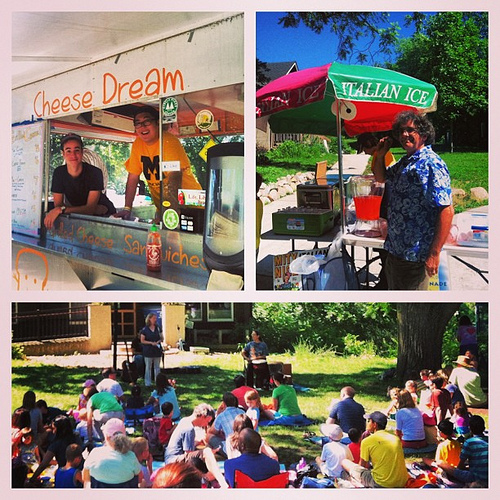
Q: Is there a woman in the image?
A: Yes, there is a woman.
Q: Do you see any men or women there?
A: Yes, there is a woman.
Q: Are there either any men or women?
A: Yes, there is a woman.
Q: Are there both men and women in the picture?
A: Yes, there are both a woman and a man.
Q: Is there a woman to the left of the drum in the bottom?
A: Yes, there is a woman to the left of the drum.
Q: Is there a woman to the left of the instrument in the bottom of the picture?
A: Yes, there is a woman to the left of the drum.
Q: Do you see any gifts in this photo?
A: No, there are no gifts.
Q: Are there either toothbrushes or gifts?
A: No, there are no gifts or toothbrushes.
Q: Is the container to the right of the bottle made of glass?
A: Yes, the container is made of glass.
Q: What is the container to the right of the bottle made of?
A: The container is made of glass.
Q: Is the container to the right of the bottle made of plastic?
A: No, the container is made of glass.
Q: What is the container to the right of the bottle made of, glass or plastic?
A: The container is made of glass.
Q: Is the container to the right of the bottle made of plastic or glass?
A: The container is made of glass.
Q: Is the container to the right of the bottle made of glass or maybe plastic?
A: The container is made of glass.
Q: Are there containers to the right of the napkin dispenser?
A: Yes, there is a container to the right of the napkin dispenser.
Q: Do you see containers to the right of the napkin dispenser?
A: Yes, there is a container to the right of the napkin dispenser.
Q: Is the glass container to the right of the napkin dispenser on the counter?
A: Yes, the container is to the right of the napkin dispenser.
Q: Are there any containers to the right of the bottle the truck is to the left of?
A: Yes, there is a container to the right of the bottle.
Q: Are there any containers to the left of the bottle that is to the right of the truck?
A: No, the container is to the right of the bottle.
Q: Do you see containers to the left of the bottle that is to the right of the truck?
A: No, the container is to the right of the bottle.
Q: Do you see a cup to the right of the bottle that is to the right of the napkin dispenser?
A: No, there is a container to the right of the bottle.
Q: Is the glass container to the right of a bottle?
A: Yes, the container is to the right of a bottle.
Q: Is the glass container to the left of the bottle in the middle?
A: No, the container is to the right of the bottle.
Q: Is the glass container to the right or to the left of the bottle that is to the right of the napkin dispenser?
A: The container is to the right of the bottle.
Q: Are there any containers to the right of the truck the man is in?
A: Yes, there is a container to the right of the truck.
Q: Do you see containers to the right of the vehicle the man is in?
A: Yes, there is a container to the right of the truck.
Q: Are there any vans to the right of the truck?
A: No, there is a container to the right of the truck.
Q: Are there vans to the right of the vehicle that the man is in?
A: No, there is a container to the right of the truck.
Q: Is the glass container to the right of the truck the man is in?
A: Yes, the container is to the right of the truck.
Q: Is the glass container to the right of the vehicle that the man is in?
A: Yes, the container is to the right of the truck.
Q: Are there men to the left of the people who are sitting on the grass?
A: Yes, there is a man to the left of the people.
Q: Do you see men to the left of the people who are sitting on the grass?
A: Yes, there is a man to the left of the people.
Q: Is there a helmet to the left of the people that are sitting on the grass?
A: No, there is a man to the left of the people.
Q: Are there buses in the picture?
A: No, there are no buses.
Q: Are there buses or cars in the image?
A: No, there are no buses or cars.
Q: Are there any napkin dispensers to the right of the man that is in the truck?
A: Yes, there is a napkin dispenser to the right of the man.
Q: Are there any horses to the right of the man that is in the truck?
A: No, there is a napkin dispenser to the right of the man.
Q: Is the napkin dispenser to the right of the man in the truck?
A: Yes, the napkin dispenser is to the right of the man.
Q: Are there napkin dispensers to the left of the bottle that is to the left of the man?
A: Yes, there is a napkin dispenser to the left of the bottle.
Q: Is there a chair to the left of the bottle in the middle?
A: No, there is a napkin dispenser to the left of the bottle.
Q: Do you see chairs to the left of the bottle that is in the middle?
A: No, there is a napkin dispenser to the left of the bottle.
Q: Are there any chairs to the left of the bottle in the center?
A: No, there is a napkin dispenser to the left of the bottle.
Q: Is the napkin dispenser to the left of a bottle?
A: Yes, the napkin dispenser is to the left of a bottle.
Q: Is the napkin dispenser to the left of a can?
A: No, the napkin dispenser is to the left of a bottle.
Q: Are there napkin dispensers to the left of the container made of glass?
A: Yes, there is a napkin dispenser to the left of the container.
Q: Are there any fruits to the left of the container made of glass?
A: No, there is a napkin dispenser to the left of the container.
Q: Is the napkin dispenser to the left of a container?
A: Yes, the napkin dispenser is to the left of a container.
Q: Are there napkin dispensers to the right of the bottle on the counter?
A: Yes, there is a napkin dispenser to the right of the bottle.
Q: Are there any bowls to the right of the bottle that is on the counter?
A: No, there is a napkin dispenser to the right of the bottle.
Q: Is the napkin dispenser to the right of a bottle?
A: Yes, the napkin dispenser is to the right of a bottle.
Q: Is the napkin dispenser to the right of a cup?
A: No, the napkin dispenser is to the right of a bottle.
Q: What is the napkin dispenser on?
A: The napkin dispenser is on the counter.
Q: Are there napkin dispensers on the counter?
A: Yes, there is a napkin dispenser on the counter.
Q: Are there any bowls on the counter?
A: No, there is a napkin dispenser on the counter.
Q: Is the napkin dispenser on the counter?
A: Yes, the napkin dispenser is on the counter.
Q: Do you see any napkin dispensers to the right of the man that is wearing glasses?
A: Yes, there is a napkin dispenser to the right of the man.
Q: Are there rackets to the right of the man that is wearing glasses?
A: No, there is a napkin dispenser to the right of the man.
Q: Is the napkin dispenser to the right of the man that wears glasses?
A: Yes, the napkin dispenser is to the right of the man.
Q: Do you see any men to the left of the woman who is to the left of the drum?
A: Yes, there is a man to the left of the woman.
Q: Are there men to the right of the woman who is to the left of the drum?
A: No, the man is to the left of the woman.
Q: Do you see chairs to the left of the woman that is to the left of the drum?
A: No, there is a man to the left of the woman.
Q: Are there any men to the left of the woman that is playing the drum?
A: Yes, there is a man to the left of the woman.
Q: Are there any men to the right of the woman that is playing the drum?
A: No, the man is to the left of the woman.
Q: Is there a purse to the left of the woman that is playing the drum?
A: No, there is a man to the left of the woman.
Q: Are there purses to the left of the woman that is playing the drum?
A: No, there is a man to the left of the woman.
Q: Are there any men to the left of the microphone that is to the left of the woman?
A: Yes, there is a man to the left of the microphone.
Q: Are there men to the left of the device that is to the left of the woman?
A: Yes, there is a man to the left of the microphone.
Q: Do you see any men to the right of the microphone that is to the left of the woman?
A: No, the man is to the left of the microphone.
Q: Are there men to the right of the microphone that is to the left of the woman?
A: No, the man is to the left of the microphone.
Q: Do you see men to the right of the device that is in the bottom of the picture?
A: No, the man is to the left of the microphone.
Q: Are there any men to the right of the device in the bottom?
A: No, the man is to the left of the microphone.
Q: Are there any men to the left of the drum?
A: Yes, there is a man to the left of the drum.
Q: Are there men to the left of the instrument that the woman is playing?
A: Yes, there is a man to the left of the drum.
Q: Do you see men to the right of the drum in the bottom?
A: No, the man is to the left of the drum.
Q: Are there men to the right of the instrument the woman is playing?
A: No, the man is to the left of the drum.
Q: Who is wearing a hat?
A: The man is wearing a hat.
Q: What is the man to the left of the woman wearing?
A: The man is wearing a hat.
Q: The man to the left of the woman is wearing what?
A: The man is wearing a hat.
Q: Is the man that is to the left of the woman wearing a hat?
A: Yes, the man is wearing a hat.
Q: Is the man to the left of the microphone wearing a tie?
A: No, the man is wearing a hat.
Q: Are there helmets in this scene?
A: No, there are no helmets.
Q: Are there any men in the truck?
A: Yes, there is a man in the truck.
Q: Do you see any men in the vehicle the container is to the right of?
A: Yes, there is a man in the truck.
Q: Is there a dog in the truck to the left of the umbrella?
A: No, there is a man in the truck.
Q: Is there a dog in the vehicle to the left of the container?
A: No, there is a man in the truck.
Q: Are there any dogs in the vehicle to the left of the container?
A: No, there is a man in the truck.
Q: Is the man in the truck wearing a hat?
A: Yes, the man is wearing a hat.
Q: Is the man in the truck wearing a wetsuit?
A: No, the man is wearing a hat.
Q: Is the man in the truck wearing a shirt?
A: Yes, the man is wearing a shirt.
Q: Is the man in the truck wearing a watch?
A: No, the man is wearing a shirt.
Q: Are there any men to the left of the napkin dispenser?
A: Yes, there is a man to the left of the napkin dispenser.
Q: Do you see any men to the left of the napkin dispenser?
A: Yes, there is a man to the left of the napkin dispenser.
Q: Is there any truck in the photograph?
A: Yes, there is a truck.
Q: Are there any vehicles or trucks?
A: Yes, there is a truck.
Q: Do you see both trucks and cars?
A: No, there is a truck but no cars.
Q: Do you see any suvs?
A: No, there are no suvs.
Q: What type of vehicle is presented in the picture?
A: The vehicle is a truck.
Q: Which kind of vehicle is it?
A: The vehicle is a truck.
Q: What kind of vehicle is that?
A: This is a truck.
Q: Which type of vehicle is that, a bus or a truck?
A: This is a truck.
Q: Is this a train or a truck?
A: This is a truck.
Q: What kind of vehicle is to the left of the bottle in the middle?
A: The vehicle is a truck.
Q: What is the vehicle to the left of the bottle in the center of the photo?
A: The vehicle is a truck.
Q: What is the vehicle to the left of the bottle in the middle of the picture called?
A: The vehicle is a truck.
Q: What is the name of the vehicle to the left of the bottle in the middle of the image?
A: The vehicle is a truck.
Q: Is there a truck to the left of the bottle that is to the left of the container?
A: Yes, there is a truck to the left of the bottle.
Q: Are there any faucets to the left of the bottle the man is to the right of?
A: No, there is a truck to the left of the bottle.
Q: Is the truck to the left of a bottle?
A: Yes, the truck is to the left of a bottle.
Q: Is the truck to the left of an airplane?
A: No, the truck is to the left of a bottle.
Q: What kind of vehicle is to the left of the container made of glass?
A: The vehicle is a truck.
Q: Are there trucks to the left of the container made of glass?
A: Yes, there is a truck to the left of the container.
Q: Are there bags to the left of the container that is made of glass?
A: No, there is a truck to the left of the container.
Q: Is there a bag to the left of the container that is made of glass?
A: No, there is a truck to the left of the container.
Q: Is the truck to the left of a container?
A: Yes, the truck is to the left of a container.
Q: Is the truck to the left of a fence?
A: No, the truck is to the left of a container.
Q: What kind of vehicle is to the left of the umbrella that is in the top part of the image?
A: The vehicle is a truck.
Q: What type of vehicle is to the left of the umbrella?
A: The vehicle is a truck.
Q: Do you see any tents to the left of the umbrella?
A: No, there is a truck to the left of the umbrella.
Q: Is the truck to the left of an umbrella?
A: Yes, the truck is to the left of an umbrella.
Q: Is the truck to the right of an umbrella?
A: No, the truck is to the left of an umbrella.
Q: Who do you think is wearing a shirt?
A: The man is wearing a shirt.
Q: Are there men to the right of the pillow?
A: No, the man is to the left of the pillow.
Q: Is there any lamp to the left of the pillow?
A: No, there is a man to the left of the pillow.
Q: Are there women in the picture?
A: Yes, there is a woman.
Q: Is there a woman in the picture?
A: Yes, there is a woman.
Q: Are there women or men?
A: Yes, there is a woman.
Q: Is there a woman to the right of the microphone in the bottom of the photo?
A: Yes, there is a woman to the right of the microphone.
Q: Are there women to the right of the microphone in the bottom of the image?
A: Yes, there is a woman to the right of the microphone.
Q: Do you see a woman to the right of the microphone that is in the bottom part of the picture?
A: Yes, there is a woman to the right of the microphone.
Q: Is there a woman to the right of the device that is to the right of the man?
A: Yes, there is a woman to the right of the microphone.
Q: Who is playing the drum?
A: The woman is playing the drum.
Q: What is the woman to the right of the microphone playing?
A: The woman is playing the drum.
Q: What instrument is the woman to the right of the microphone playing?
A: The woman is playing the drum.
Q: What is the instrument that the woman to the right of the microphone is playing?
A: The instrument is a drum.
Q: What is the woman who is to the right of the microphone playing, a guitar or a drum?
A: The woman is playing a drum.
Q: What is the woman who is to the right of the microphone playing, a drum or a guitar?
A: The woman is playing a drum.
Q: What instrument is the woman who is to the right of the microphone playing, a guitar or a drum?
A: The woman is playing a drum.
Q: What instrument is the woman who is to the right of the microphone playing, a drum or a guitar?
A: The woman is playing a drum.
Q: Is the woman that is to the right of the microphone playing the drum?
A: Yes, the woman is playing the drum.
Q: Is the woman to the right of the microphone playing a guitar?
A: No, the woman is playing the drum.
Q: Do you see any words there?
A: Yes, there are words.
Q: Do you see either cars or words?
A: Yes, there are words.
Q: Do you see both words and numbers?
A: No, there are words but no numbers.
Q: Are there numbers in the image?
A: No, there are no numbers.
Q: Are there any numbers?
A: No, there are no numbers.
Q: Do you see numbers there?
A: No, there are no numbers.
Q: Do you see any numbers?
A: No, there are no numbers.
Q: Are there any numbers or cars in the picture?
A: No, there are no numbers or cars.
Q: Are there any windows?
A: Yes, there is a window.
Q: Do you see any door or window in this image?
A: Yes, there is a window.